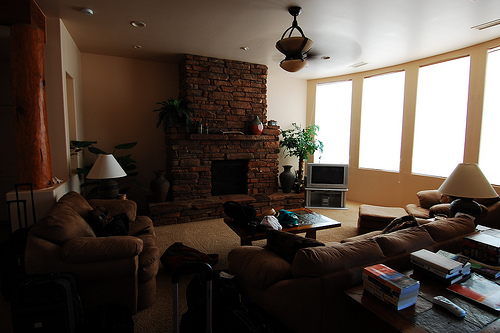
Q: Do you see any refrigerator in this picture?
A: No, there are no refrigerators.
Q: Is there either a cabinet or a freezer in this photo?
A: No, there are no refrigerators or cabinets.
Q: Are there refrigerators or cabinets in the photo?
A: No, there are no refrigerators or cabinets.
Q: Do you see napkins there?
A: No, there are no napkins.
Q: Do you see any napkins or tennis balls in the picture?
A: No, there are no napkins or tennis balls.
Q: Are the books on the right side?
A: Yes, the books are on the right of the image.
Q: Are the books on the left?
A: No, the books are on the right of the image.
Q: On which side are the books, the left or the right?
A: The books are on the right of the image.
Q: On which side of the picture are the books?
A: The books are on the right of the image.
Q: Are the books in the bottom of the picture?
A: Yes, the books are in the bottom of the image.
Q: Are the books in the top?
A: No, the books are in the bottom of the image.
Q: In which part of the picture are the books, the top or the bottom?
A: The books are in the bottom of the image.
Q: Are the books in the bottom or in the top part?
A: The books are in the bottom of the image.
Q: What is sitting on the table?
A: The books are sitting on the table.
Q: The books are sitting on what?
A: The books are sitting on the table.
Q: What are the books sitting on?
A: The books are sitting on the table.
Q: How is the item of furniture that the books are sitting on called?
A: The piece of furniture is a table.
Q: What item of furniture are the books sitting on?
A: The books are sitting on the table.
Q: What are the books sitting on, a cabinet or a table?
A: The books are sitting on a table.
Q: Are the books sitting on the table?
A: Yes, the books are sitting on the table.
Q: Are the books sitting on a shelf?
A: No, the books are sitting on the table.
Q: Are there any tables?
A: Yes, there is a table.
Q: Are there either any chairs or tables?
A: Yes, there is a table.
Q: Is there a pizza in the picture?
A: No, there are no pizzas.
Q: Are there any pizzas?
A: No, there are no pizzas.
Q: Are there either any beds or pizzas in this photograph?
A: No, there are no pizzas or beds.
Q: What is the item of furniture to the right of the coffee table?
A: The piece of furniture is a table.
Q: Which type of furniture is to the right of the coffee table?
A: The piece of furniture is a table.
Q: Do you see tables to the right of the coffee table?
A: Yes, there is a table to the right of the coffee table.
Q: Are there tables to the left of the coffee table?
A: No, the table is to the right of the coffee table.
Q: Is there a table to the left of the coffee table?
A: No, the table is to the right of the coffee table.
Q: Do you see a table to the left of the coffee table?
A: No, the table is to the right of the coffee table.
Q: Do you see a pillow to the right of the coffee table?
A: No, there is a table to the right of the coffee table.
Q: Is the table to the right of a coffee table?
A: Yes, the table is to the right of a coffee table.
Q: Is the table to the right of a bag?
A: No, the table is to the right of a coffee table.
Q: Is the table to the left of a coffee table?
A: No, the table is to the right of a coffee table.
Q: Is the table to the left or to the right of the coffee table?
A: The table is to the right of the coffee table.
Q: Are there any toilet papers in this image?
A: No, there are no toilet papers.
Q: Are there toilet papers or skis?
A: No, there are no toilet papers or skis.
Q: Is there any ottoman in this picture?
A: Yes, there is an ottoman.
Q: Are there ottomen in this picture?
A: Yes, there is an ottoman.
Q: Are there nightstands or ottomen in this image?
A: Yes, there is an ottoman.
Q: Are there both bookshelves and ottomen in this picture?
A: No, there is an ottoman but no bookshelves.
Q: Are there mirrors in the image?
A: No, there are no mirrors.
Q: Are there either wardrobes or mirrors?
A: No, there are no mirrors or wardrobes.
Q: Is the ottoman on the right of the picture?
A: Yes, the ottoman is on the right of the image.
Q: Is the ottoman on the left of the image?
A: No, the ottoman is on the right of the image.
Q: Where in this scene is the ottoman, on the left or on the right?
A: The ottoman is on the right of the image.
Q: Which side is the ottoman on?
A: The ottoman is on the right of the image.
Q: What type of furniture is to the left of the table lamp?
A: The piece of furniture is an ottoman.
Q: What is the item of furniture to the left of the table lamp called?
A: The piece of furniture is an ottoman.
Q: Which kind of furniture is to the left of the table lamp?
A: The piece of furniture is an ottoman.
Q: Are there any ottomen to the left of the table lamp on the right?
A: Yes, there is an ottoman to the left of the table lamp.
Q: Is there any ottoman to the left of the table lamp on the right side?
A: Yes, there is an ottoman to the left of the table lamp.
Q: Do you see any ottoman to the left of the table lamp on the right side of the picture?
A: Yes, there is an ottoman to the left of the table lamp.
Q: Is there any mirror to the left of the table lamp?
A: No, there is an ottoman to the left of the table lamp.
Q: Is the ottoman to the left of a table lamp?
A: Yes, the ottoman is to the left of a table lamp.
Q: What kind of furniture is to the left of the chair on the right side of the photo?
A: The piece of furniture is an ottoman.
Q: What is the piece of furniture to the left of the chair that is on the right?
A: The piece of furniture is an ottoman.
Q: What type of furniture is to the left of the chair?
A: The piece of furniture is an ottoman.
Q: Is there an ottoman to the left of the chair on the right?
A: Yes, there is an ottoman to the left of the chair.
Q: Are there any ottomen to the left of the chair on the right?
A: Yes, there is an ottoman to the left of the chair.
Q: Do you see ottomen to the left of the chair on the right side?
A: Yes, there is an ottoman to the left of the chair.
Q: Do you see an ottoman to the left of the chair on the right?
A: Yes, there is an ottoman to the left of the chair.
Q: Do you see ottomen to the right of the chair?
A: No, the ottoman is to the left of the chair.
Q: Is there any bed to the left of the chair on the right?
A: No, there is an ottoman to the left of the chair.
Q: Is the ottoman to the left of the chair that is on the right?
A: Yes, the ottoman is to the left of the chair.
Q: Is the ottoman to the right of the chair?
A: No, the ottoman is to the left of the chair.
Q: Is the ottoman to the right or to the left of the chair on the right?
A: The ottoman is to the left of the chair.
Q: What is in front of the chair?
A: The ottoman is in front of the chair.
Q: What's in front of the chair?
A: The ottoman is in front of the chair.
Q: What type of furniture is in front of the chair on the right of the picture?
A: The piece of furniture is an ottoman.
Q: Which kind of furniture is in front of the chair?
A: The piece of furniture is an ottoman.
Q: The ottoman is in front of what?
A: The ottoman is in front of the chair.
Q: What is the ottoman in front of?
A: The ottoman is in front of the chair.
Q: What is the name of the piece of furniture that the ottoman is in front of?
A: The piece of furniture is a chair.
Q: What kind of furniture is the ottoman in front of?
A: The ottoman is in front of the chair.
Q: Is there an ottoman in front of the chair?
A: Yes, there is an ottoman in front of the chair.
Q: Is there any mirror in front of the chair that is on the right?
A: No, there is an ottoman in front of the chair.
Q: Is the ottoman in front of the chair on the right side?
A: Yes, the ottoman is in front of the chair.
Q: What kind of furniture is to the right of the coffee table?
A: The piece of furniture is an ottoman.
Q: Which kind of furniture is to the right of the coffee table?
A: The piece of furniture is an ottoman.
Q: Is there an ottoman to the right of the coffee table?
A: Yes, there is an ottoman to the right of the coffee table.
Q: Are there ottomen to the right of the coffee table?
A: Yes, there is an ottoman to the right of the coffee table.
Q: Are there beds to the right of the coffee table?
A: No, there is an ottoman to the right of the coffee table.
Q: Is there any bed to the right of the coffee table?
A: No, there is an ottoman to the right of the coffee table.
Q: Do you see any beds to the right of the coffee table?
A: No, there is an ottoman to the right of the coffee table.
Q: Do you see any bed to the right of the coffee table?
A: No, there is an ottoman to the right of the coffee table.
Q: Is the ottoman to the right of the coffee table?
A: Yes, the ottoman is to the right of the coffee table.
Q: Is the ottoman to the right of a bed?
A: No, the ottoman is to the right of the coffee table.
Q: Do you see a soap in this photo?
A: No, there are no soaps.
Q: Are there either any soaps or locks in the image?
A: No, there are no soaps or locks.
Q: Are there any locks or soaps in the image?
A: No, there are no soaps or locks.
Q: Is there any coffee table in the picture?
A: Yes, there is a coffee table.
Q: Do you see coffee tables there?
A: Yes, there is a coffee table.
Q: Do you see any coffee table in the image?
A: Yes, there is a coffee table.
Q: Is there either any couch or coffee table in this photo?
A: Yes, there is a coffee table.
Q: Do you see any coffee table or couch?
A: Yes, there is a coffee table.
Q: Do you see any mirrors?
A: No, there are no mirrors.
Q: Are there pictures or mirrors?
A: No, there are no mirrors or pictures.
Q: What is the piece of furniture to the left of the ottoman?
A: The piece of furniture is a coffee table.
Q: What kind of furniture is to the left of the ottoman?
A: The piece of furniture is a coffee table.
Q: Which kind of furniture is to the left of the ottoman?
A: The piece of furniture is a coffee table.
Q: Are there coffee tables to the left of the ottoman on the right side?
A: Yes, there is a coffee table to the left of the ottoman.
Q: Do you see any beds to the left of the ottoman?
A: No, there is a coffee table to the left of the ottoman.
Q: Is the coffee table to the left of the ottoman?
A: Yes, the coffee table is to the left of the ottoman.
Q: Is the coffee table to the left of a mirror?
A: No, the coffee table is to the left of the ottoman.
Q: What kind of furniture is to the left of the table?
A: The piece of furniture is a coffee table.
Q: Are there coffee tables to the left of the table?
A: Yes, there is a coffee table to the left of the table.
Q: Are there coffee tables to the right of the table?
A: No, the coffee table is to the left of the table.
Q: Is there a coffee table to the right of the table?
A: No, the coffee table is to the left of the table.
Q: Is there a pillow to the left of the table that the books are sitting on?
A: No, there is a coffee table to the left of the table.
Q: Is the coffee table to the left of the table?
A: Yes, the coffee table is to the left of the table.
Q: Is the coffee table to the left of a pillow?
A: No, the coffee table is to the left of the table.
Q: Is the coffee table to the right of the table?
A: No, the coffee table is to the left of the table.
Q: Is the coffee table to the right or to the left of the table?
A: The coffee table is to the left of the table.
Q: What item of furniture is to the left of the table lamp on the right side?
A: The piece of furniture is a coffee table.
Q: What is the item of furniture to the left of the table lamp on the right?
A: The piece of furniture is a coffee table.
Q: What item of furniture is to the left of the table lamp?
A: The piece of furniture is a coffee table.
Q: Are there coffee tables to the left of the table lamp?
A: Yes, there is a coffee table to the left of the table lamp.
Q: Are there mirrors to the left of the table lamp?
A: No, there is a coffee table to the left of the table lamp.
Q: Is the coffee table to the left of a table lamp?
A: Yes, the coffee table is to the left of a table lamp.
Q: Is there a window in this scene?
A: Yes, there is a window.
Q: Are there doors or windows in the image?
A: Yes, there is a window.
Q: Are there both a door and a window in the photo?
A: No, there is a window but no doors.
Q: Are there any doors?
A: No, there are no doors.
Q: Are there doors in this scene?
A: No, there are no doors.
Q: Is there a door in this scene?
A: No, there are no doors.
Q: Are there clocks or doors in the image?
A: No, there are no doors or clocks.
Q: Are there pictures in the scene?
A: No, there are no pictures.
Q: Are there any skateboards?
A: No, there are no skateboards.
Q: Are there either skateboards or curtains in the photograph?
A: No, there are no skateboards or curtains.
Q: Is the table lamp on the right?
A: Yes, the table lamp is on the right of the image.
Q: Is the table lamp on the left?
A: No, the table lamp is on the right of the image.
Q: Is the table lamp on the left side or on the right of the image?
A: The table lamp is on the right of the image.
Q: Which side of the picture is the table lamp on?
A: The table lamp is on the right of the image.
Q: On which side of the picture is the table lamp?
A: The table lamp is on the right of the image.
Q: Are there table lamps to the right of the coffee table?
A: Yes, there is a table lamp to the right of the coffee table.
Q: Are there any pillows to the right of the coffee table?
A: No, there is a table lamp to the right of the coffee table.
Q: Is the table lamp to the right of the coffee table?
A: Yes, the table lamp is to the right of the coffee table.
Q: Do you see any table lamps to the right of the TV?
A: Yes, there is a table lamp to the right of the TV.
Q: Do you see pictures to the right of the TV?
A: No, there is a table lamp to the right of the TV.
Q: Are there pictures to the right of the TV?
A: No, there is a table lamp to the right of the TV.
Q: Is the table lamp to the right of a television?
A: Yes, the table lamp is to the right of a television.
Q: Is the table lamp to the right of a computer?
A: No, the table lamp is to the right of a television.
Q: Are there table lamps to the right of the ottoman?
A: Yes, there is a table lamp to the right of the ottoman.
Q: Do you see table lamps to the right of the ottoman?
A: Yes, there is a table lamp to the right of the ottoman.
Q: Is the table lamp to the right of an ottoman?
A: Yes, the table lamp is to the right of an ottoman.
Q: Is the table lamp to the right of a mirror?
A: No, the table lamp is to the right of an ottoman.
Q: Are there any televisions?
A: Yes, there is a television.